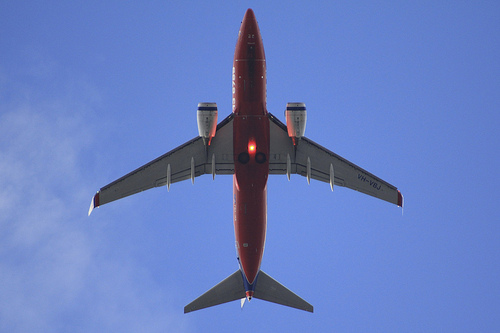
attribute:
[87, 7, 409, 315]
plane — large, big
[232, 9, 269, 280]
body — red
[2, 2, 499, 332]
sky — blue, clear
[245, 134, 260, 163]
light — red, lit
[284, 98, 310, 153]
engine — large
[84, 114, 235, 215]
wing — large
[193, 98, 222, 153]
engine — large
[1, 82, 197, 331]
cloud — white